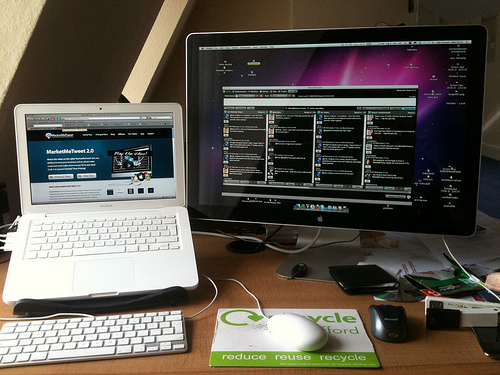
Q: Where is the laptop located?
A: Desk.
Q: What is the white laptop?
A: Computer.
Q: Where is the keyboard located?
A: Desk.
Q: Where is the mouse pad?
A: Desk.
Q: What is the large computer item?
A: Monitor.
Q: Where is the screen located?
A: Laptop.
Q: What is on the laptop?
A: Keyboard.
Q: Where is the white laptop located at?
A: Desk.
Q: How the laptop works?
A: Charging.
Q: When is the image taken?
A: Used.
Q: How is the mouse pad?
A: White and green.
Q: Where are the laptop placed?
A: On table.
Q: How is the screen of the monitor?
A: Wide.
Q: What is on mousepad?
A: Mouse.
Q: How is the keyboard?
A: Clear.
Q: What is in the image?
A: Computer workstation.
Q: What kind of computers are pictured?
A: Laptop and desktop.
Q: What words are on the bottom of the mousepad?
A: Reduce reuse recycle.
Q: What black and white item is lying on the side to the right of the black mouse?
A: Stapler.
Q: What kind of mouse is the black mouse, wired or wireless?
A: Wireless.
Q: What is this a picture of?
A: Computers.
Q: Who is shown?
A: No one.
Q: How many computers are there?
A: Two.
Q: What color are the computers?
A: Black and white.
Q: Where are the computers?
A: On the desk.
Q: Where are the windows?
A: On the left wall.